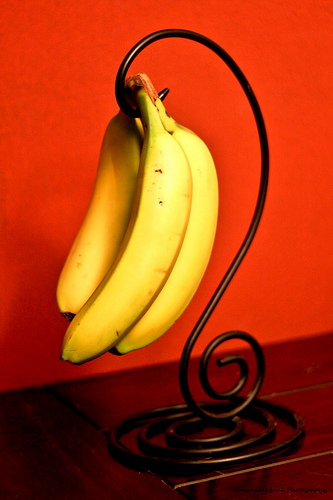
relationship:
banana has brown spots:
[59, 75, 193, 366] [60, 74, 193, 365]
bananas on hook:
[57, 73, 219, 365] [107, 28, 171, 118]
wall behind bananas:
[1, 0, 331, 395] [57, 73, 219, 365]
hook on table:
[107, 28, 171, 118] [1, 332, 332, 500]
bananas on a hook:
[57, 73, 219, 365] [107, 28, 171, 118]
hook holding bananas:
[107, 28, 171, 118] [57, 73, 219, 365]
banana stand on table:
[107, 29, 305, 469] [1, 332, 332, 500]